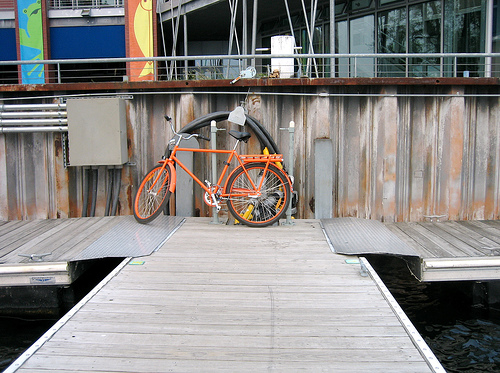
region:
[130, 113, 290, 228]
Bicycle against wall is orange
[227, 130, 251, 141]
Black seat on bicycle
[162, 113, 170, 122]
Black handle bar on bicycle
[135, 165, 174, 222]
Black tire on bicycle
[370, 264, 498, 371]
Water next to wooden pier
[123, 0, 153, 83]
Fish banner above bicycle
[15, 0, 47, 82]
Frog banner above bicycle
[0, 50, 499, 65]
Metal pole above bicycle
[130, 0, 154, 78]
Fish on banner is yellow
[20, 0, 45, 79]
Frog on banner is green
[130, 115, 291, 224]
An orange bike on the pier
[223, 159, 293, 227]
The rear tire on the bike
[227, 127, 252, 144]
The bike's black seat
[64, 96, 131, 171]
A large electrical box on the wall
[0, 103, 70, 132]
Silver pipes leading into the box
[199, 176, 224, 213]
Metal pedals on the bike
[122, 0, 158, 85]
An orange sign with a yellow fish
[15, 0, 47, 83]
A blue banner with a green frog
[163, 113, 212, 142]
The handlebars on the bike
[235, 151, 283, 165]
A basket on the rear of the bike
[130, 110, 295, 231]
painted orange metal bicycle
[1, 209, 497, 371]
wooden dock over water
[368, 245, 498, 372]
dark coloured rippling water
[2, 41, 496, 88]
grey metal guard rail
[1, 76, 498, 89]
rusty strip of metal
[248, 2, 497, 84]
row of tall glass windows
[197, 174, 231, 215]
shiny silver metal bike pedals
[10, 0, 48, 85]
tall banner of a green frog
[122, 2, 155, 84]
tall banner of a yellow fish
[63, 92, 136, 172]
tan coloured metal box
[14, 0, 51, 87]
A blue panel with a green painted frog on it.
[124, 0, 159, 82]
An orange panel with a yellow fish painted on it.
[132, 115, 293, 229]
An orange bicycle on a dock.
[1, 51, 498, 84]
A gray metal railing.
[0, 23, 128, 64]
A section of a blue painted wall.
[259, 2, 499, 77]
Windows overlooking a dock.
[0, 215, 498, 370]
A T shaped wooden dock.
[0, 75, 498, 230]
A metal sea wall behind a dock.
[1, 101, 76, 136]
Four silver metal pipes.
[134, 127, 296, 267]
this is a bike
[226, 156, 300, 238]
the wheel of a bike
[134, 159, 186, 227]
the wheel of a bike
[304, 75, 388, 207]
this is made of iron sheets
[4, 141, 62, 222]
this is made of iron sheets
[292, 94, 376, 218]
this is made of iron sheets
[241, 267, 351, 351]
this is made of wood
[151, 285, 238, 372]
this is made of wood